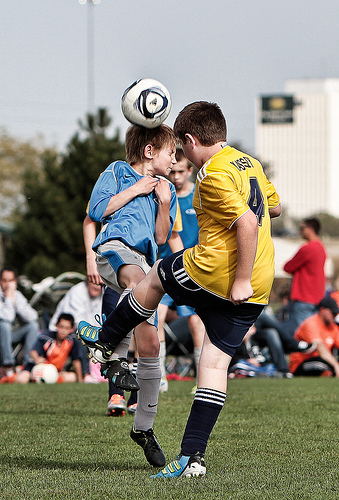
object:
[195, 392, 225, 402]
stripe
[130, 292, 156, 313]
stripes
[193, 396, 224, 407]
stripe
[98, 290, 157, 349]
sock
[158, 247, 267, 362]
shorts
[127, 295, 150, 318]
stripe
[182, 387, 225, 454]
sock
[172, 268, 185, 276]
stripe